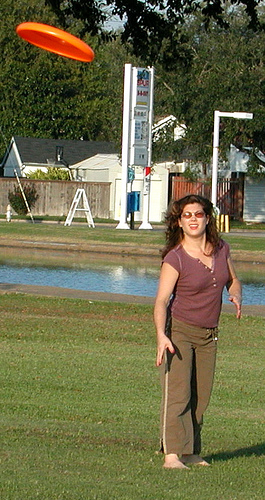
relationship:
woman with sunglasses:
[141, 179, 259, 495] [176, 207, 205, 225]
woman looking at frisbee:
[141, 179, 259, 495] [11, 14, 111, 73]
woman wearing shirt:
[141, 179, 259, 495] [159, 251, 230, 335]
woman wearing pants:
[141, 179, 259, 495] [163, 321, 214, 453]